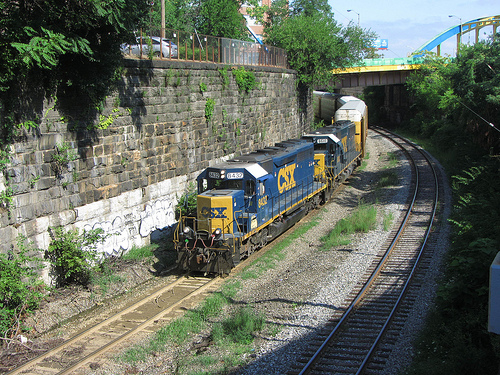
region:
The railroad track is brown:
[311, 244, 425, 373]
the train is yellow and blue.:
[167, 184, 280, 262]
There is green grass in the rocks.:
[214, 275, 245, 370]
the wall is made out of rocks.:
[119, 144, 189, 196]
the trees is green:
[417, 71, 498, 200]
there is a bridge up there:
[331, 64, 414, 77]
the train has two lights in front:
[173, 223, 227, 236]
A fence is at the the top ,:
[173, 43, 271, 60]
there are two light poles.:
[346, 1, 469, 28]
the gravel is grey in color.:
[272, 224, 380, 282]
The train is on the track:
[162, 85, 371, 281]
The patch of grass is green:
[176, 303, 278, 349]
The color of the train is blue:
[235, 138, 317, 220]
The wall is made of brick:
[28, 88, 162, 266]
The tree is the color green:
[8, 8, 132, 63]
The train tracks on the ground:
[348, 218, 424, 359]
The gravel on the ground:
[268, 250, 340, 316]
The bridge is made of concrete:
[353, 53, 428, 119]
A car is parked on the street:
[122, 27, 184, 62]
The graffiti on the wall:
[82, 200, 149, 259]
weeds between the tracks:
[317, 197, 392, 259]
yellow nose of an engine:
[197, 193, 232, 233]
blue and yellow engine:
[175, 135, 325, 277]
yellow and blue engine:
[169, 135, 328, 277]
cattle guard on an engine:
[162, 245, 232, 277]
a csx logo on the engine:
[275, 164, 298, 194]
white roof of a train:
[336, 96, 368, 121]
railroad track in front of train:
[12, 274, 218, 373]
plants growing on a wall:
[217, 67, 260, 96]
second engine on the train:
[302, 117, 359, 189]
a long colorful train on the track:
[180, 90, 370, 279]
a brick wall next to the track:
[2, 55, 329, 282]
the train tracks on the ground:
[34, 117, 443, 374]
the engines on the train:
[168, 120, 368, 260]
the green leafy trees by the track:
[405, 50, 496, 210]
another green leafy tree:
[5, 4, 147, 76]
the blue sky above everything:
[349, 3, 488, 54]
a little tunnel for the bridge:
[327, 86, 412, 123]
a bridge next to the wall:
[331, 58, 422, 88]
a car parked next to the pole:
[128, 31, 180, 58]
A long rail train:
[175, 94, 367, 274]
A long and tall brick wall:
[0, 60, 316, 293]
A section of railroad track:
[295, 124, 445, 374]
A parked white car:
[121, 33, 179, 56]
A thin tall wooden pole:
[161, 0, 165, 56]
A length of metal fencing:
[124, 28, 288, 66]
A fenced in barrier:
[124, 27, 288, 67]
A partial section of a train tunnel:
[338, 65, 433, 127]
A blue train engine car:
[176, 140, 323, 274]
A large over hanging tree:
[0, 0, 155, 87]